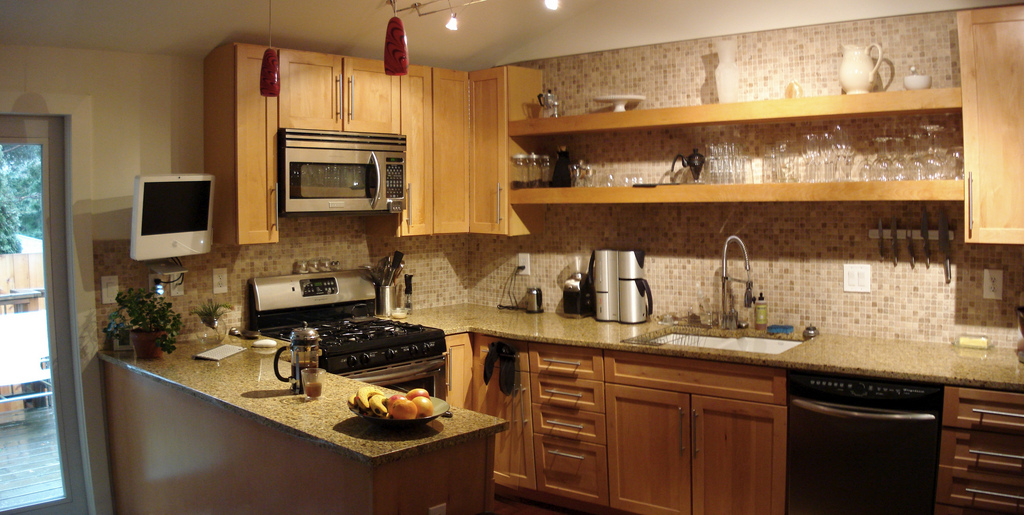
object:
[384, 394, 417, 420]
orange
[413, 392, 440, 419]
orange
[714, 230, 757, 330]
faucet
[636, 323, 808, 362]
sink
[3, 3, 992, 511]
kitchen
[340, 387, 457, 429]
basket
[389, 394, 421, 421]
fruit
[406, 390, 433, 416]
fruit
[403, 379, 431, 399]
fruit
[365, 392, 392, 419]
fruit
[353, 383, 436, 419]
fruit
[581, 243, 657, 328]
coffee maker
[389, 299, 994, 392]
counter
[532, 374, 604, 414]
drawer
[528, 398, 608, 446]
drawer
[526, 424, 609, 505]
drawer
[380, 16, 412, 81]
lamp shade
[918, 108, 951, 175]
glass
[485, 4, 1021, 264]
shelf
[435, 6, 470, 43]
lights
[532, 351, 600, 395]
drawer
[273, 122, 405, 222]
microwave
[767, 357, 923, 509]
dishwasher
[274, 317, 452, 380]
burners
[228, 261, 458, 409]
stove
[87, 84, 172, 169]
wall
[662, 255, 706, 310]
wall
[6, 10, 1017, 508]
building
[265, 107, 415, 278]
one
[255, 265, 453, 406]
one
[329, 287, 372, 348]
stovetop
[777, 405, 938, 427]
handle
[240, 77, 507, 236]
drawers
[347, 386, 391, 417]
bananas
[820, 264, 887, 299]
white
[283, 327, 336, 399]
juice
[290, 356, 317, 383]
glass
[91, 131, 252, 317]
screen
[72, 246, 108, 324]
wall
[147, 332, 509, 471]
counter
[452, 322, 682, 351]
counter top